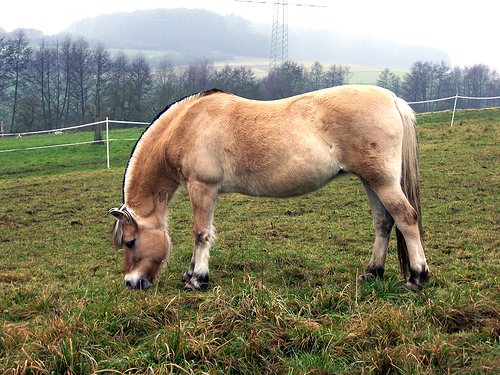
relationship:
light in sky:
[247, 1, 392, 59] [286, 9, 313, 27]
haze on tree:
[75, 43, 115, 99] [88, 57, 119, 106]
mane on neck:
[152, 79, 203, 122] [116, 136, 191, 207]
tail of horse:
[411, 121, 435, 190] [84, 39, 454, 306]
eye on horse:
[114, 229, 140, 262] [84, 39, 454, 306]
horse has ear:
[107, 83, 434, 294] [104, 201, 144, 238]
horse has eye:
[107, 83, 434, 294] [114, 229, 140, 262]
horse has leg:
[107, 83, 434, 294] [176, 182, 243, 304]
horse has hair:
[107, 83, 434, 294] [128, 110, 195, 152]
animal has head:
[84, 39, 454, 306] [103, 189, 184, 281]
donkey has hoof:
[84, 39, 454, 306] [177, 212, 222, 301]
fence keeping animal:
[25, 114, 117, 186] [84, 39, 454, 306]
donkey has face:
[84, 39, 454, 306] [117, 228, 159, 280]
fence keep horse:
[25, 114, 117, 186] [84, 39, 454, 306]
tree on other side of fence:
[88, 57, 119, 106] [25, 114, 117, 186]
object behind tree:
[268, 0, 290, 72] [88, 57, 119, 106]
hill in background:
[160, 56, 265, 111] [147, 18, 355, 131]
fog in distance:
[144, 3, 354, 94] [76, 28, 393, 186]